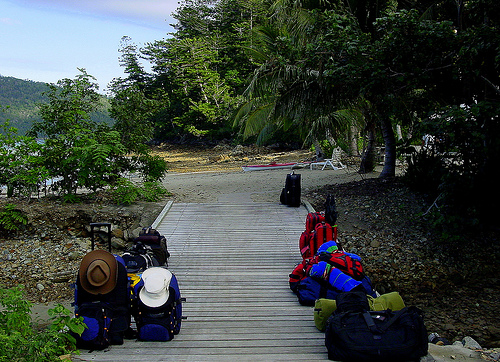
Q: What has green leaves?
A: Brown tree.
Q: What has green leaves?
A: The brown tree.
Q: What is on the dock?
A: Luggage.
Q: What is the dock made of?
A: Wood.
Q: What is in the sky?
A: Clouds.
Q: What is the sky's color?
A: Blue.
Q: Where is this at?
A: A park.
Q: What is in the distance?
A: Trees.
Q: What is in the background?
A: Hills.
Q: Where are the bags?
A: On the ground.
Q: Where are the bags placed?
A: On pavement.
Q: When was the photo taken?
A: Daylight.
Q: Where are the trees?
A: Side of pavement.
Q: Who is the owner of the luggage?
A: Travelers.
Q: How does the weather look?
A: Cloudy.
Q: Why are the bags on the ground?
A: Travelers resting.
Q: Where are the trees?
A: Lining beach.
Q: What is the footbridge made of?
A: Wood.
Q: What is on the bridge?
A: Bags.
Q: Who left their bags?
A: Travelers.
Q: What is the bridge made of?
A: Wood.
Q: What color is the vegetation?
A: Green.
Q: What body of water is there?
A: Ocean.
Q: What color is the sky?
A: Blue.